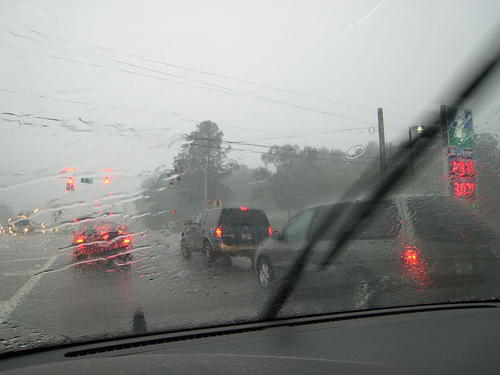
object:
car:
[71, 220, 134, 275]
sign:
[439, 105, 473, 148]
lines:
[0, 254, 57, 326]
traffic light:
[61, 165, 112, 190]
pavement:
[0, 229, 500, 342]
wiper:
[263, 56, 500, 319]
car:
[179, 205, 272, 271]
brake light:
[398, 244, 434, 293]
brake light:
[214, 227, 222, 238]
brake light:
[268, 226, 273, 237]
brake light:
[125, 239, 129, 242]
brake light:
[77, 239, 84, 243]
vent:
[65, 305, 498, 357]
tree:
[173, 120, 240, 211]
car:
[6, 214, 33, 237]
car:
[254, 195, 500, 310]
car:
[0, 0, 500, 374]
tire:
[257, 255, 274, 290]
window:
[219, 208, 270, 224]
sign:
[447, 147, 478, 214]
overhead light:
[54, 162, 78, 193]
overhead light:
[101, 167, 115, 189]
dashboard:
[2, 300, 500, 372]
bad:
[0, 0, 500, 352]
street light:
[415, 124, 425, 134]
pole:
[409, 127, 414, 178]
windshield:
[0, 1, 497, 361]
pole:
[378, 108, 388, 178]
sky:
[0, 0, 500, 226]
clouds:
[0, 0, 500, 228]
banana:
[255, 193, 500, 309]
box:
[280, 194, 499, 290]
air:
[64, 143, 115, 170]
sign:
[80, 178, 93, 185]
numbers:
[450, 155, 475, 203]